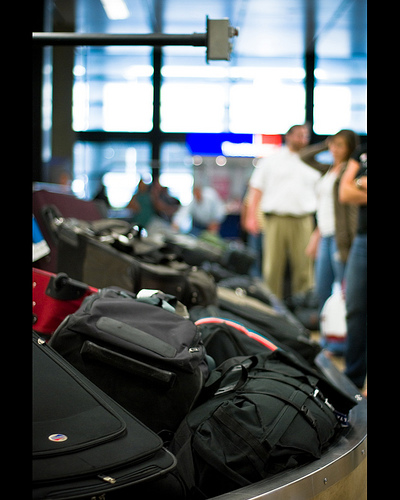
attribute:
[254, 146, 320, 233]
shirt — white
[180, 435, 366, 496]
rack — silver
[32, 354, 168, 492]
suitcase — black, rolling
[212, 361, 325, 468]
bag — black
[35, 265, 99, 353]
suitcase — red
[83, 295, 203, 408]
suitcase — black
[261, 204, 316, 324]
pants — tan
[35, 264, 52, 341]
luggage — red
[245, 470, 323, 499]
side — silver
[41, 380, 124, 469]
luggage — black, rectangular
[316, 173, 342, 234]
shirt — white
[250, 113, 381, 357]
people — watching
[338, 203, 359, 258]
shirt — brown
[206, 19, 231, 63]
camera — grey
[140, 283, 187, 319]
tag — white